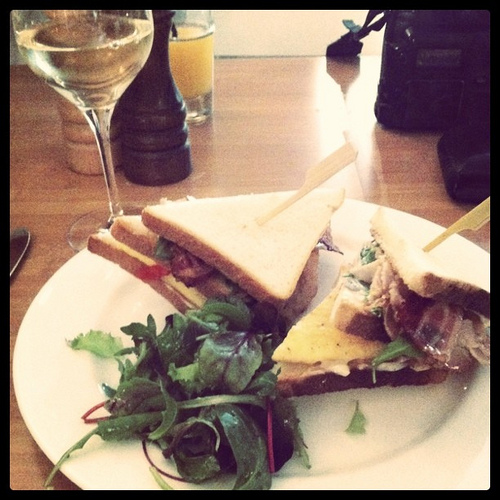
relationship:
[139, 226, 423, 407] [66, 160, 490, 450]
sandwich on plate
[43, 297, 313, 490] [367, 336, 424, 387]
salad has leaf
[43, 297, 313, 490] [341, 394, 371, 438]
salad has leaf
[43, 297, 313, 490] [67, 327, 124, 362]
salad has leaf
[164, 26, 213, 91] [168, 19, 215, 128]
orange drink in glass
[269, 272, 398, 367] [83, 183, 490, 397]
cheese on sandwich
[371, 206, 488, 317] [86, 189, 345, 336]
bread on sandwich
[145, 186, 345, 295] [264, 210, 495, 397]
bread on sandwich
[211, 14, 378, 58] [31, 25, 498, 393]
wall by table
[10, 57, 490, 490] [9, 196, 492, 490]
table beneath dinner plate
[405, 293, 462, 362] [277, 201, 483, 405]
bacon on sandwich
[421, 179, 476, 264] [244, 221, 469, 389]
toothpick on sandwich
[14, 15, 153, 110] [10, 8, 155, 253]
wine in glass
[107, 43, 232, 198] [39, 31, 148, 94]
pepper grinder behind wine